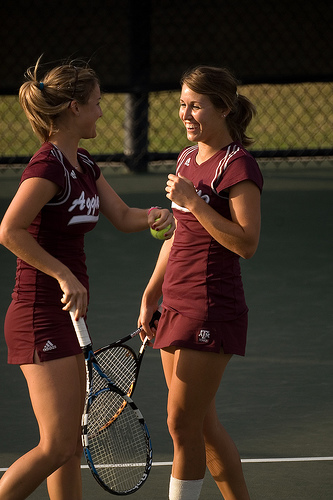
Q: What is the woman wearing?
A: Tennis outfit.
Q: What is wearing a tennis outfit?
A: A woman.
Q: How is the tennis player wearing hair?
A: Ponytail.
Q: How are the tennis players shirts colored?
A: Maroon.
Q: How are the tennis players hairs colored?
A: Blonde and brunette.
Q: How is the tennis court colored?
A: Black.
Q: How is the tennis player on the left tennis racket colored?
A: Blue, black, and white.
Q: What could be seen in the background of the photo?
A: Grass.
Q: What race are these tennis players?
A: Caucasian.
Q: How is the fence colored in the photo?
A: Black.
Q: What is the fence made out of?
A: Iron.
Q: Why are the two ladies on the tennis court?
A: Training.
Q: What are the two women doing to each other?
A: Smiling.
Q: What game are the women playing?
A: Tennis.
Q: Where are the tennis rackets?
A: In the women's hands.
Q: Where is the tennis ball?
A: In the woman's hand.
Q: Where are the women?
A: On a tennis court.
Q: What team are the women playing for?
A: Aggies.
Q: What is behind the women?
A: A fence.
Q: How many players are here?
A: Two.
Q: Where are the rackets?
A: In the player's hands.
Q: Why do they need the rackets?
A: To hit the tennis balls.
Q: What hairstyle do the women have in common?
A: Ponytails.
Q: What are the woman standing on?
A: A tennis court.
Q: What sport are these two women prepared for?
A: Tennis.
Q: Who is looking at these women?
A: The photographer.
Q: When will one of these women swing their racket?
A: When it is time to hit the ball.